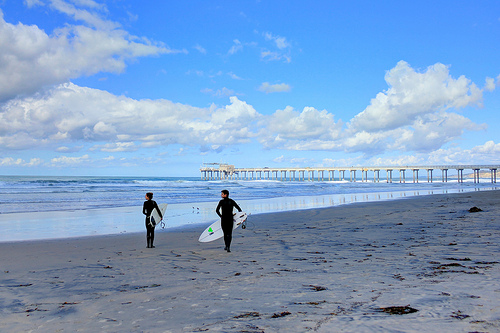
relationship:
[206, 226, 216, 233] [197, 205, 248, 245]
green on surfboard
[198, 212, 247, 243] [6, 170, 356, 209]
board being carried to water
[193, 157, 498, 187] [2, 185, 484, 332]
pier on beach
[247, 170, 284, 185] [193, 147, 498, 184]
waves crash against pier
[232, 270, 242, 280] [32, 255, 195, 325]
footprint in sand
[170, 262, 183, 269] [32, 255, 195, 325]
footprint in sand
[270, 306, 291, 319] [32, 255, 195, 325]
footprint in sand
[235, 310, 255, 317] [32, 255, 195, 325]
footprint in sand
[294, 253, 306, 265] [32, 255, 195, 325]
footprint in sand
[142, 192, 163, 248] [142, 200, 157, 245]
surfer in wetsuit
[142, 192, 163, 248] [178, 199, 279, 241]
surfer holding surfboard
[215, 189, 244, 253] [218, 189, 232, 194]
man with dark hair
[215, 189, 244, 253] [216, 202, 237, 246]
man in wetsuit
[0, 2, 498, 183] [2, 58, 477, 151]
sky with cloud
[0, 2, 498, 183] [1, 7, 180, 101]
sky with cloud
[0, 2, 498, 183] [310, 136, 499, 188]
sky with cloud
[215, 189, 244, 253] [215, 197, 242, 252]
man in wetsuit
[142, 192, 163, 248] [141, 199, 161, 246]
surfer in wetsuit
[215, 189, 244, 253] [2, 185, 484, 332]
man on beach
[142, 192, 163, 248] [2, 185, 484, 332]
surfer on beach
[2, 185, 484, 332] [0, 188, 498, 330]
beach with sand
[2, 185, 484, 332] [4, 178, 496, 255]
beach with water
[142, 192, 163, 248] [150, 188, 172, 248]
surfer with surfboards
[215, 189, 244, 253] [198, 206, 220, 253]
man with surfboards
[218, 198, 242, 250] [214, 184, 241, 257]
wetsuit on surfer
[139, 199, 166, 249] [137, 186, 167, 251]
wet suit on surfer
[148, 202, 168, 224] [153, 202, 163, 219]
board on surfer's arm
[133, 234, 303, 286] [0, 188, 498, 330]
foot steps in sand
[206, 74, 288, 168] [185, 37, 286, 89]
cloud in sky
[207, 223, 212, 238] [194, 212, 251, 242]
sticker on surfboard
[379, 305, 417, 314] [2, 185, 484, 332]
seaweed on beach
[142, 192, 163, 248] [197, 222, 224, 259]
surfer holding surfboard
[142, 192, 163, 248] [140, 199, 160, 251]
surfer in wetsuit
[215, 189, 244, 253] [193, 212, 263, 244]
man carrying board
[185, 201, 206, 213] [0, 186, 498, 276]
birds on beach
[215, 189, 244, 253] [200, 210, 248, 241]
man on surfboard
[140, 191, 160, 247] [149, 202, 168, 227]
surfer on board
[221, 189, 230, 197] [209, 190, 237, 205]
dark hair on head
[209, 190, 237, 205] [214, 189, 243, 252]
head on man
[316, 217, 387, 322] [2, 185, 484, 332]
sand area of beach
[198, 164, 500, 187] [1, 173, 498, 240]
pier in water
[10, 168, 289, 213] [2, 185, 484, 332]
water on beach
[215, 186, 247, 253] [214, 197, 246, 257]
man wearing wetsuit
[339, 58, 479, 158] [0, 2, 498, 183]
cloud in sky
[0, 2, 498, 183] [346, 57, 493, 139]
sky filled with clouds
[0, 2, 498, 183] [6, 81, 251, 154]
sky filled with clouds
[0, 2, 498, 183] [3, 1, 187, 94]
sky filled with clouds